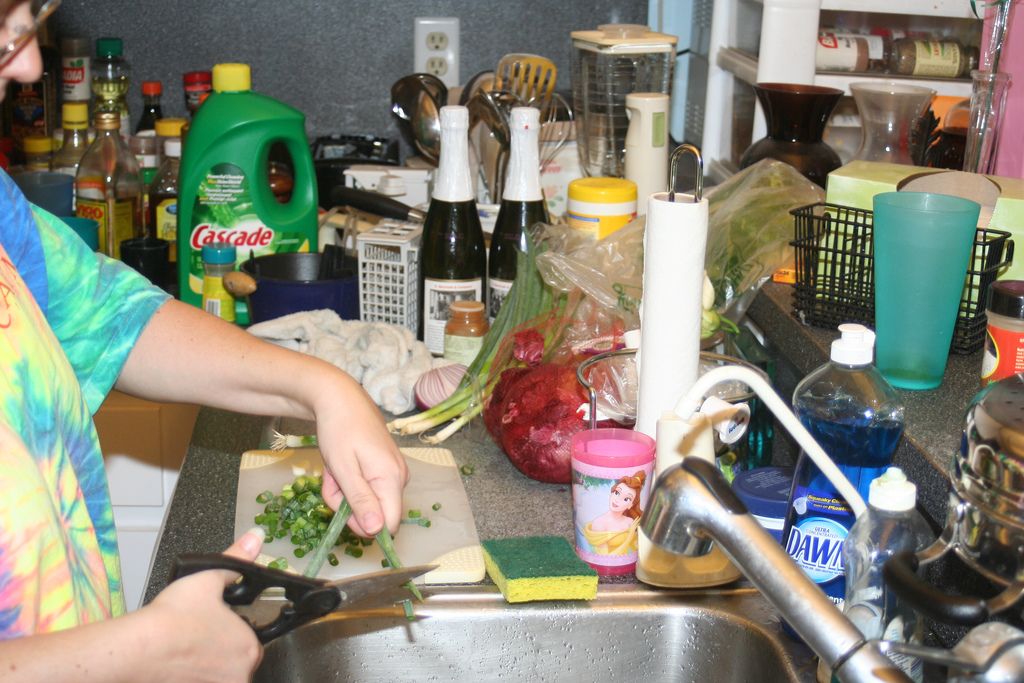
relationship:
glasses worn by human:
[5, 10, 59, 61] [7, 1, 410, 673]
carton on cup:
[571, 474, 657, 552] [571, 430, 657, 574]